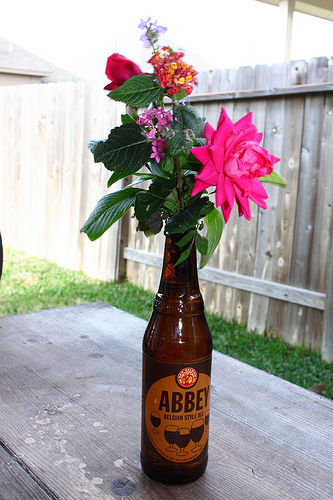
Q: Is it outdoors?
A: Yes, it is outdoors.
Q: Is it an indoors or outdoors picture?
A: It is outdoors.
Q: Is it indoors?
A: No, it is outdoors.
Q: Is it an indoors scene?
A: No, it is outdoors.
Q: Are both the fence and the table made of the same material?
A: Yes, both the fence and the table are made of wood.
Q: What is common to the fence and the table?
A: The material, both the fence and the table are wooden.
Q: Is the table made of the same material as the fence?
A: Yes, both the table and the fence are made of wood.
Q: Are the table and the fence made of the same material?
A: Yes, both the table and the fence are made of wood.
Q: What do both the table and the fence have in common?
A: The material, both the table and the fence are wooden.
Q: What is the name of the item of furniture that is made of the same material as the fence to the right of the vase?
A: The piece of furniture is a table.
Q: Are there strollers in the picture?
A: No, there are no strollers.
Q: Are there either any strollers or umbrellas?
A: No, there are no strollers or umbrellas.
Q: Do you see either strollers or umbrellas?
A: No, there are no strollers or umbrellas.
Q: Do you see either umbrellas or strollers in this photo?
A: No, there are no strollers or umbrellas.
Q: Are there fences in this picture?
A: Yes, there is a fence.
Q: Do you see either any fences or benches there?
A: Yes, there is a fence.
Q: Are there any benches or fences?
A: Yes, there is a fence.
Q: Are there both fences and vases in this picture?
A: Yes, there are both a fence and a vase.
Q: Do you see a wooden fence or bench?
A: Yes, there is a wood fence.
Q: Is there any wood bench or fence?
A: Yes, there is a wood fence.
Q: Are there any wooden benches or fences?
A: Yes, there is a wood fence.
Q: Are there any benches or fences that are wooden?
A: Yes, the fence is wooden.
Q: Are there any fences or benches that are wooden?
A: Yes, the fence is wooden.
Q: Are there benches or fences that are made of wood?
A: Yes, the fence is made of wood.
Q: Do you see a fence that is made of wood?
A: Yes, there is a fence that is made of wood.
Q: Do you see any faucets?
A: No, there are no faucets.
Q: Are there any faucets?
A: No, there are no faucets.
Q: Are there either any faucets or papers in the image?
A: No, there are no faucets or papers.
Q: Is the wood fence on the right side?
A: Yes, the fence is on the right of the image.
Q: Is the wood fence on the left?
A: No, the fence is on the right of the image.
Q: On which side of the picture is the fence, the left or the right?
A: The fence is on the right of the image.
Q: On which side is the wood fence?
A: The fence is on the right of the image.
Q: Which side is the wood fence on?
A: The fence is on the right of the image.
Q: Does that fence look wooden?
A: Yes, the fence is wooden.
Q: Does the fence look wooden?
A: Yes, the fence is wooden.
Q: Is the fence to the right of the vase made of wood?
A: Yes, the fence is made of wood.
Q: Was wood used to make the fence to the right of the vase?
A: Yes, the fence is made of wood.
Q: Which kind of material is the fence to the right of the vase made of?
A: The fence is made of wood.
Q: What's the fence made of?
A: The fence is made of wood.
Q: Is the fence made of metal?
A: No, the fence is made of wood.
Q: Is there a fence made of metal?
A: No, there is a fence but it is made of wood.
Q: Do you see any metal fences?
A: No, there is a fence but it is made of wood.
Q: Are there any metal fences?
A: No, there is a fence but it is made of wood.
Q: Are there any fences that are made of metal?
A: No, there is a fence but it is made of wood.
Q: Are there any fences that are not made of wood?
A: No, there is a fence but it is made of wood.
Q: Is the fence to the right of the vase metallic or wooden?
A: The fence is wooden.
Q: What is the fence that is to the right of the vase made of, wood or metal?
A: The fence is made of wood.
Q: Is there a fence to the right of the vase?
A: Yes, there is a fence to the right of the vase.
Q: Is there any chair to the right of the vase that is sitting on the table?
A: No, there is a fence to the right of the vase.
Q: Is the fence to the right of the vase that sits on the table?
A: Yes, the fence is to the right of the vase.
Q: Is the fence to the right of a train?
A: No, the fence is to the right of the vase.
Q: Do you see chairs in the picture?
A: No, there are no chairs.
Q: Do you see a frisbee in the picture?
A: No, there are no frisbees.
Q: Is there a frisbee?
A: No, there are no frisbees.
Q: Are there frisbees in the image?
A: No, there are no frisbees.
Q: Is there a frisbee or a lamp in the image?
A: No, there are no frisbees or lamps.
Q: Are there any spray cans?
A: No, there are no spray cans.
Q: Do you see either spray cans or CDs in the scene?
A: No, there are no spray cans or cds.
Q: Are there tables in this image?
A: Yes, there is a table.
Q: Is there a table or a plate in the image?
A: Yes, there is a table.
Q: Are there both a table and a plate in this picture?
A: No, there is a table but no plates.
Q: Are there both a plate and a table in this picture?
A: No, there is a table but no plates.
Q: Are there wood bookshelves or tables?
A: Yes, there is a wood table.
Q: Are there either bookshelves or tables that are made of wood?
A: Yes, the table is made of wood.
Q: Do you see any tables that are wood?
A: Yes, there is a wood table.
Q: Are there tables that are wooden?
A: Yes, there is a table that is wooden.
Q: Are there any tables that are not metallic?
A: Yes, there is a wooden table.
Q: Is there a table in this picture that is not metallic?
A: Yes, there is a wooden table.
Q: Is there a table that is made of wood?
A: Yes, there is a table that is made of wood.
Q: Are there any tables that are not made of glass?
A: Yes, there is a table that is made of wood.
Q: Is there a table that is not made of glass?
A: Yes, there is a table that is made of wood.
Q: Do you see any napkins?
A: No, there are no napkins.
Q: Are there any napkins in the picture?
A: No, there are no napkins.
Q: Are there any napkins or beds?
A: No, there are no napkins or beds.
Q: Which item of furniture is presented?
A: The piece of furniture is a table.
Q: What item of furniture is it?
A: The piece of furniture is a table.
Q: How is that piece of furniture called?
A: That is a table.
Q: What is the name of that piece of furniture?
A: That is a table.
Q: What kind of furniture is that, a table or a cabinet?
A: That is a table.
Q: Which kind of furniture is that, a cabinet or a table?
A: That is a table.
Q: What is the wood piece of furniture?
A: The piece of furniture is a table.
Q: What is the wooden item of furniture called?
A: The piece of furniture is a table.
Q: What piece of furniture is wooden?
A: The piece of furniture is a table.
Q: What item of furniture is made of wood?
A: The piece of furniture is a table.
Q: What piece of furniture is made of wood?
A: The piece of furniture is a table.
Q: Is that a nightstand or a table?
A: That is a table.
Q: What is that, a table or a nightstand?
A: That is a table.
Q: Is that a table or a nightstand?
A: That is a table.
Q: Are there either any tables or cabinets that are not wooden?
A: No, there is a table but it is wooden.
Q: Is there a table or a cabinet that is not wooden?
A: No, there is a table but it is wooden.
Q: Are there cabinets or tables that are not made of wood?
A: No, there is a table but it is made of wood.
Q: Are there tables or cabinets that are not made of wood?
A: No, there is a table but it is made of wood.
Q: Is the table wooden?
A: Yes, the table is wooden.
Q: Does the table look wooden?
A: Yes, the table is wooden.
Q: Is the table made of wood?
A: Yes, the table is made of wood.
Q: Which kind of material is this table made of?
A: The table is made of wood.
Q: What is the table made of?
A: The table is made of wood.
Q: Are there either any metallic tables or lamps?
A: No, there is a table but it is wooden.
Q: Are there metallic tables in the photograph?
A: No, there is a table but it is wooden.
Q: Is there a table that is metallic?
A: No, there is a table but it is wooden.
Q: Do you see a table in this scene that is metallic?
A: No, there is a table but it is wooden.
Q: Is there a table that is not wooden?
A: No, there is a table but it is wooden.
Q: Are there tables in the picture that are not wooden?
A: No, there is a table but it is wooden.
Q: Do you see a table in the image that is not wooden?
A: No, there is a table but it is wooden.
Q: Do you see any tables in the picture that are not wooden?
A: No, there is a table but it is wooden.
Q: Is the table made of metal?
A: No, the table is made of wood.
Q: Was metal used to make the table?
A: No, the table is made of wood.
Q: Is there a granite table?
A: No, there is a table but it is made of wood.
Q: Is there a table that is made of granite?
A: No, there is a table but it is made of wood.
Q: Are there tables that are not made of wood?
A: No, there is a table but it is made of wood.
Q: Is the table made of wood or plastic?
A: The table is made of wood.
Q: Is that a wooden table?
A: Yes, that is a wooden table.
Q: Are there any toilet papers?
A: No, there are no toilet papers.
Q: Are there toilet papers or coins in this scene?
A: No, there are no toilet papers or coins.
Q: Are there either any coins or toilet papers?
A: No, there are no toilet papers or coins.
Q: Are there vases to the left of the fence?
A: Yes, there is a vase to the left of the fence.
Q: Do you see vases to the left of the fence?
A: Yes, there is a vase to the left of the fence.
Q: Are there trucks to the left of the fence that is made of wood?
A: No, there is a vase to the left of the fence.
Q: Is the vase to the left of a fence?
A: Yes, the vase is to the left of a fence.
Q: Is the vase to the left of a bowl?
A: No, the vase is to the left of a fence.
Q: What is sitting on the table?
A: The vase is sitting on the table.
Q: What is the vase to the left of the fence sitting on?
A: The vase is sitting on the table.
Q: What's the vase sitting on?
A: The vase is sitting on the table.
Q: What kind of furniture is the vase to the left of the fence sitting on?
A: The vase is sitting on the table.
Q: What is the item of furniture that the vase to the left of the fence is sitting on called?
A: The piece of furniture is a table.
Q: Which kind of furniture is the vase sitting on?
A: The vase is sitting on the table.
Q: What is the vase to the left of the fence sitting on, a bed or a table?
A: The vase is sitting on a table.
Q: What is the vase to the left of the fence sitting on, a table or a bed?
A: The vase is sitting on a table.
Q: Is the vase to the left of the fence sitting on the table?
A: Yes, the vase is sitting on the table.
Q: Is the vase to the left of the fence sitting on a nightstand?
A: No, the vase is sitting on the table.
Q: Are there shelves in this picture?
A: No, there are no shelves.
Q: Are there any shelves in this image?
A: No, there are no shelves.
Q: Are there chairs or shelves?
A: No, there are no shelves or chairs.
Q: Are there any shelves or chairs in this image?
A: No, there are no shelves or chairs.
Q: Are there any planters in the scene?
A: No, there are no planters.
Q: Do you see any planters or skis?
A: No, there are no planters or skis.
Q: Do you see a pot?
A: No, there are no pots.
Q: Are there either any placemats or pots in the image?
A: No, there are no pots or placemats.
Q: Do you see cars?
A: No, there are no cars.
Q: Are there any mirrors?
A: No, there are no mirrors.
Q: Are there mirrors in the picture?
A: No, there are no mirrors.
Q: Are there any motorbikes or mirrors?
A: No, there are no mirrors or motorbikes.